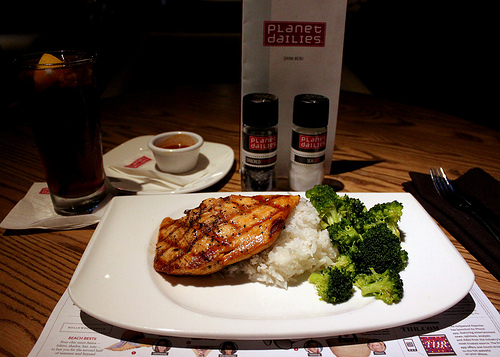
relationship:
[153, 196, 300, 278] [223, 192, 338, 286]
chicken on top of rice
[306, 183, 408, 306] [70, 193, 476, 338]
broccoli on plate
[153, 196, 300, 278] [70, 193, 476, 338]
chicken on plate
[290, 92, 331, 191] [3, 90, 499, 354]
salt on table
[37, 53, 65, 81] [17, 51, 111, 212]
lemon in glass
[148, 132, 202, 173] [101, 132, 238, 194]
sauce on saucer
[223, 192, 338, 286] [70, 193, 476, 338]
rice on plate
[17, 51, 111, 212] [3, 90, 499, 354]
glass on table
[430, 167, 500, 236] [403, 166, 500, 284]
fork on napkin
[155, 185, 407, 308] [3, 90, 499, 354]
dinner on table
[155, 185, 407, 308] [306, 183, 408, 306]
meal has broccoli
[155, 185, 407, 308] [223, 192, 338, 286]
meal has rice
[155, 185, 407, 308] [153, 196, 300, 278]
meal has chicken